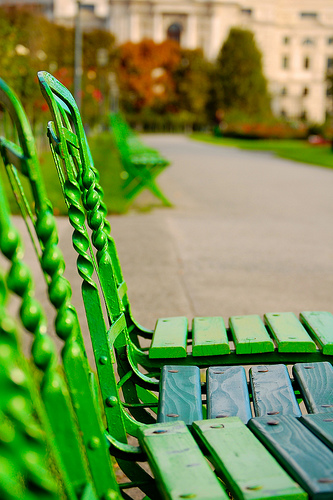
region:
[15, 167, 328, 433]
green chairs are visible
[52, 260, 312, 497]
green chairs are visible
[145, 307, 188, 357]
a green plank of wood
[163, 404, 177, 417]
a bolt on the seat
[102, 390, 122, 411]
a green bolt on the back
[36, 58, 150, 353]
the green back of a chair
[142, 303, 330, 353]
the green seat of a chair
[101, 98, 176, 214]
a green chair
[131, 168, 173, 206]
the leg of a chair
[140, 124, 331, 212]
a gray paved road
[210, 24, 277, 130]
a green tree in the background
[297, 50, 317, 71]
a window on the building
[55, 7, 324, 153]
stately white building behind trees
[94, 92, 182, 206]
green chairs facing a paved path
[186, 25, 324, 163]
lawn extending from cone-shaped tree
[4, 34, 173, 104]
muted red and yellow glowing colors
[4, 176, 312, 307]
path between sets of chairs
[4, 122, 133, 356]
painted strings behind the chairs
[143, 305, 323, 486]
blue and green slats covering chair seats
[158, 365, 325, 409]
grain of wood visible through blue stain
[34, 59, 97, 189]
handles as part of the backs of chairs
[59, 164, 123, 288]
metal twisted into swirls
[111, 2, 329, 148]
a stately building in the background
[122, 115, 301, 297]
a beautiful landscaped driveway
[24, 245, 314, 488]
a set of three chairs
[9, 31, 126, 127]
beautiful shrubbery along the driveway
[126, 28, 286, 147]
trees and bushes aligning the driveway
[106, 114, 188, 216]
another set of chairs in the distance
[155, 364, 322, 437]
wooden chair seats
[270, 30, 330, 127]
windows on the building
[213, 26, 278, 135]
a tall tree standing in the distance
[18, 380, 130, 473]
wooden chair backs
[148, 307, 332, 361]
the seat of a chair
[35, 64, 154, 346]
the back of a chair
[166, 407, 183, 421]
a bolt on the chair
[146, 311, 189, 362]
a plank of green wood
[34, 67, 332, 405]
a green chair on the sidewalk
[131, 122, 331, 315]
a gray sidewalk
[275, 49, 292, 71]
a window on the building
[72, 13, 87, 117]
a gray pole on the grass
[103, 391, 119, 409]
a green bolt